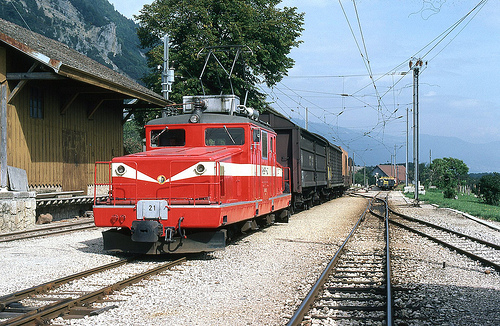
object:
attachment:
[129, 218, 159, 244]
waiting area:
[0, 20, 172, 231]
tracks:
[346, 222, 364, 245]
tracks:
[444, 226, 473, 244]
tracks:
[113, 265, 183, 288]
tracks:
[13, 224, 48, 234]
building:
[0, 7, 177, 188]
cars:
[301, 131, 329, 190]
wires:
[352, 0, 367, 31]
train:
[92, 94, 356, 253]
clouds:
[251, 37, 498, 123]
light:
[192, 161, 208, 175]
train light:
[114, 162, 126, 174]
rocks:
[148, 277, 192, 305]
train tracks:
[135, 262, 172, 279]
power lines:
[331, 0, 353, 29]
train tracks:
[285, 280, 330, 325]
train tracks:
[12, 273, 76, 298]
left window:
[202, 126, 246, 148]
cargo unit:
[260, 113, 355, 207]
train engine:
[93, 112, 292, 254]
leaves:
[151, 5, 166, 13]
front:
[92, 112, 290, 255]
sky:
[116, 0, 494, 190]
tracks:
[278, 248, 346, 324]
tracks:
[440, 243, 483, 262]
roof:
[3, 9, 173, 106]